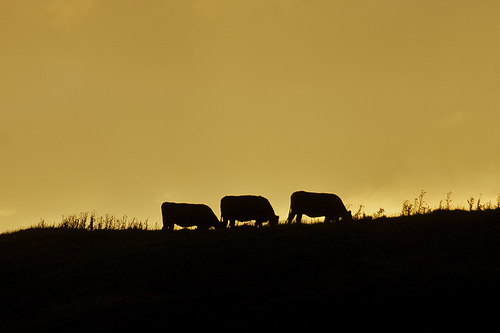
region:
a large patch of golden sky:
[0, 0, 499, 235]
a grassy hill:
[0, 206, 499, 331]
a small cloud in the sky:
[430, 109, 485, 126]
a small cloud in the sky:
[0, 205, 17, 216]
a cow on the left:
[160, 200, 225, 229]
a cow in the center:
[219, 194, 279, 227]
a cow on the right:
[285, 190, 352, 223]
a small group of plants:
[399, 188, 431, 217]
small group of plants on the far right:
[466, 192, 491, 212]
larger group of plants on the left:
[58, 208, 148, 230]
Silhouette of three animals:
[145, 173, 370, 255]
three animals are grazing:
[142, 174, 369, 259]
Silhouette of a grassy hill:
[2, 200, 496, 312]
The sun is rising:
[32, 139, 497, 278]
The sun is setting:
[0, 153, 496, 298]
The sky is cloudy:
[5, 6, 497, 236]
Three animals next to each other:
[153, 183, 360, 272]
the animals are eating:
[106, 172, 363, 267]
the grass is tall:
[35, 183, 479, 245]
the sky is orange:
[27, 10, 494, 248]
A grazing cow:
[284, 190, 355, 225]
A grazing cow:
[220, 193, 280, 225]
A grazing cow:
[160, 200, 221, 231]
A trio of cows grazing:
[160, 190, 353, 232]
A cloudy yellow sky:
[1, 0, 495, 235]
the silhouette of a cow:
[285, 188, 355, 228]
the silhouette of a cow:
[219, 193, 279, 228]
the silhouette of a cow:
[160, 200, 222, 231]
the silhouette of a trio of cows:
[159, 188, 350, 229]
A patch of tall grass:
[31, 205, 160, 232]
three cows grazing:
[140, 162, 392, 254]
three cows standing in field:
[137, 183, 364, 259]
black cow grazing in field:
[285, 175, 363, 243]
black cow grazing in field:
[220, 178, 288, 257]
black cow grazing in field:
[158, 191, 222, 244]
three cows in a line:
[120, 183, 366, 251]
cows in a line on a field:
[102, 160, 382, 260]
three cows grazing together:
[141, 166, 377, 267]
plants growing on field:
[55, 205, 146, 240]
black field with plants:
[92, 236, 380, 308]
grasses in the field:
[398, 196, 413, 223]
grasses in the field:
[416, 192, 433, 212]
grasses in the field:
[464, 198, 479, 213]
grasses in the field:
[132, 218, 142, 230]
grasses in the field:
[101, 208, 123, 229]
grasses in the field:
[88, 210, 104, 226]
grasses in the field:
[66, 212, 85, 237]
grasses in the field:
[31, 211, 48, 232]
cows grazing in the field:
[151, 171, 347, 241]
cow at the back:
[143, 189, 218, 231]